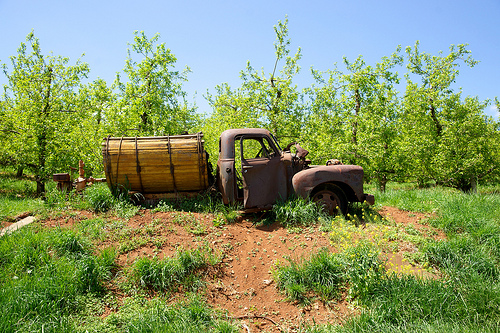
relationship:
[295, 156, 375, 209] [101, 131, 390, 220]
cab of truck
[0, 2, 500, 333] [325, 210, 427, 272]
field of flowers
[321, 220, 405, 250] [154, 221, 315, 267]
flowers in dirt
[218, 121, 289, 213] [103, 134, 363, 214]
door on truck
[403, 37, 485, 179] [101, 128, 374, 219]
tree in abandoned truck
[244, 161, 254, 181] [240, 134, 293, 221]
handle on door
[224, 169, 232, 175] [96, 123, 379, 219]
cap on truck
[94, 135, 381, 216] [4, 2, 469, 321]
car in field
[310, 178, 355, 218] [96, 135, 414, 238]
wheel of car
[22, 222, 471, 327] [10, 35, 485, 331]
grass in field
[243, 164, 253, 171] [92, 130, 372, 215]
handle of car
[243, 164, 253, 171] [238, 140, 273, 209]
handle on door